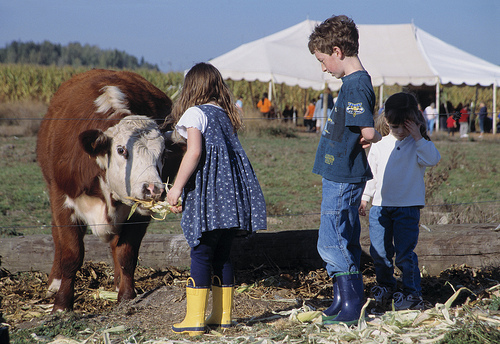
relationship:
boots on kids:
[305, 265, 372, 330] [159, 8, 446, 343]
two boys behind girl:
[289, 17, 452, 304] [165, 62, 265, 334]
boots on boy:
[319, 269, 366, 326] [304, 10, 379, 325]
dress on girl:
[177, 105, 267, 248] [165, 62, 265, 334]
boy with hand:
[359, 91, 440, 306] [402, 118, 423, 140]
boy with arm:
[304, 10, 379, 325] [341, 80, 386, 140]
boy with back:
[304, 10, 379, 325] [353, 73, 376, 178]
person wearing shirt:
[256, 90, 273, 118] [256, 95, 272, 112]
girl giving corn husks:
[162, 62, 254, 332] [122, 177, 180, 221]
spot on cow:
[92, 85, 132, 116] [32, 66, 174, 307]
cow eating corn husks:
[32, 66, 174, 307] [122, 197, 171, 221]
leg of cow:
[51, 190, 83, 310] [32, 66, 174, 307]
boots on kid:
[173, 277, 233, 336] [165, 57, 268, 338]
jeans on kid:
[363, 203, 425, 300] [355, 88, 441, 318]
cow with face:
[36, 68, 173, 335] [94, 107, 164, 206]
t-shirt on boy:
[309, 68, 378, 183] [307, 11, 384, 318]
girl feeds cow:
[152, 60, 283, 335] [23, 42, 159, 322]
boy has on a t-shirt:
[307, 11, 384, 318] [309, 68, 378, 183]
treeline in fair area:
[3, 34, 164, 79] [187, 17, 497, 154]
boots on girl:
[162, 287, 235, 341] [158, 68, 294, 339]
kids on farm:
[159, 8, 446, 343] [21, 10, 488, 341]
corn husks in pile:
[319, 266, 494, 338] [285, 286, 494, 341]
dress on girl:
[178, 101, 296, 248] [154, 53, 272, 341]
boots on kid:
[167, 272, 239, 337] [165, 57, 268, 338]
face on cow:
[105, 114, 173, 208] [30, 56, 191, 307]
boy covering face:
[359, 91, 440, 321] [373, 97, 423, 148]